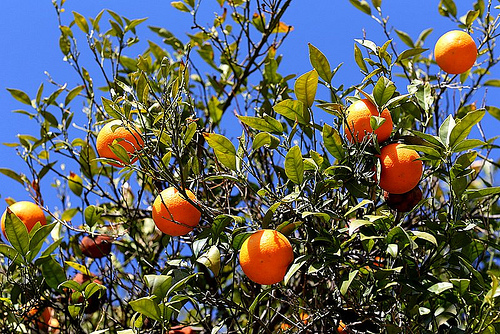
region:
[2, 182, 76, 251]
orange on orange grove tree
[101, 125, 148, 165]
orange on orange grove tree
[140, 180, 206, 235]
orange on orange grove tree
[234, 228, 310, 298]
orange on orange grove tree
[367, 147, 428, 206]
orange on orange grove tree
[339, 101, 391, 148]
orange on orange grove tree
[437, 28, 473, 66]
orange on orange grove tree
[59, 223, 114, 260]
dark orange on branch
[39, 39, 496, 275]
orange grove tree with 7 oranges shown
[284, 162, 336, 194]
green leaves on tree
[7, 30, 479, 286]
oranges growing on an orange tree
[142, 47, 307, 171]
green leaves on tree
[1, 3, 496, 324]
clear cloudless blue sky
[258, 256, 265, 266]
brown dot on orange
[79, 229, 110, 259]
dark rotten orange on tree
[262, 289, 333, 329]
twigs with no leaves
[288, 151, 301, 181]
veins on leaf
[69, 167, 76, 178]
dead brown tip on leaf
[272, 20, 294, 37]
leaf turning yellow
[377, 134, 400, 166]
shadow cast by leaf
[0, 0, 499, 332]
orange tree with lots of oranges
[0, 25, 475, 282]
oranges in a tree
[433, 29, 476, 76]
orange high in an orange tree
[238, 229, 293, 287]
shadow on side of orange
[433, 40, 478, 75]
half of orange in shadow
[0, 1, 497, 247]
blue sky behind orange tree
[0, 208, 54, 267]
green leaves under orange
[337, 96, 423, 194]
two oranges next to each other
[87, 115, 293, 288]
three oranges separated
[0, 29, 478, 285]
seven oranges in tree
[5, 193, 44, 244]
The orange on the left.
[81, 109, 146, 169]
The orange that is second to left.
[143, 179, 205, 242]
The orange that is third to the left.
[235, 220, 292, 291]
The orange in the middle.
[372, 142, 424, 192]
The bright orange on the bottom on the right.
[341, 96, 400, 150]
The orange above the bright orange on the right.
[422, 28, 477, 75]
The orange on the very top on the right.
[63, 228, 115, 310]
The rotten oranges on the left.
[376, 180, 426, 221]
The rotten orange on the right below the two oranges that are close together.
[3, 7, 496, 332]
The green leaves on the orange trees.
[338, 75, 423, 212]
two oranges on a tree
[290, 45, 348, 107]
blue sky between leaves on the tree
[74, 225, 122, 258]
rotten fruit on the tree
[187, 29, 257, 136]
branches of an orange tree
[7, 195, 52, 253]
one orange on an orange tree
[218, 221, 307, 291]
ripe fruit hanging on a tree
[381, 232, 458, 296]
thick green leaves on a tree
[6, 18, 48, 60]
blue sky near an orange tree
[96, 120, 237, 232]
oranges and leaves on a tree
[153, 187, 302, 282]
oranges ready to be picked